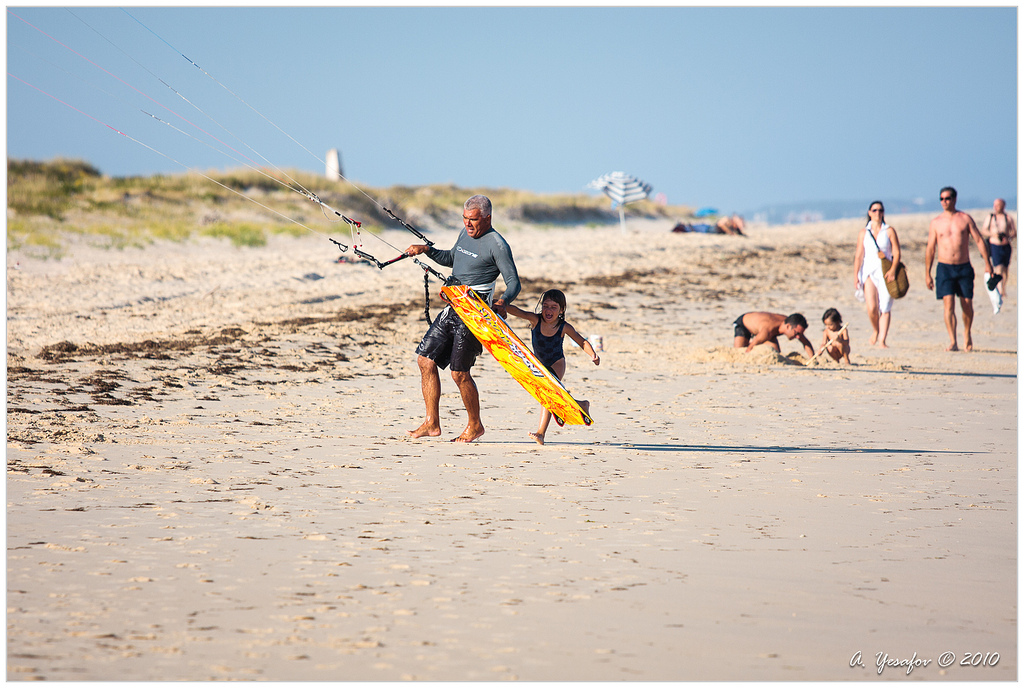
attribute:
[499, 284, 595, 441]
girl — little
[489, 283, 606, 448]
girl — little, running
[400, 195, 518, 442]
man — older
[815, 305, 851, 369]
girl — little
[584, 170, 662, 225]
umbrella — white 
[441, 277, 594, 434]
surfboard — orange 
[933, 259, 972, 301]
pants — black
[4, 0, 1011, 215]
sky — blue 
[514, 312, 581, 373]
swimsuit — black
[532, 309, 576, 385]
swimsuit — black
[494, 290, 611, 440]
girl — little